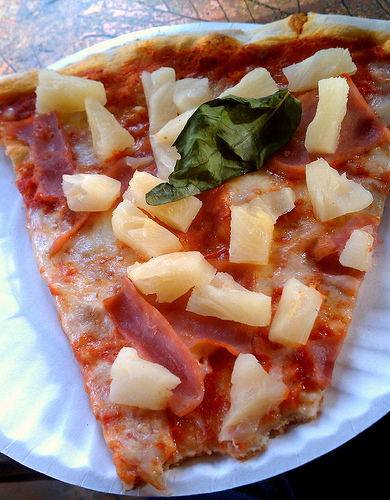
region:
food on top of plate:
[16, 9, 379, 499]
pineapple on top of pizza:
[95, 193, 317, 355]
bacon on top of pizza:
[74, 295, 199, 408]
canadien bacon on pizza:
[58, 275, 206, 403]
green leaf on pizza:
[122, 90, 308, 224]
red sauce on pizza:
[164, 387, 223, 434]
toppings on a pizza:
[59, 74, 282, 417]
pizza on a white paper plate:
[0, 25, 280, 446]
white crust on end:
[255, 10, 312, 46]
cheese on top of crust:
[290, 15, 301, 40]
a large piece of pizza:
[13, 39, 381, 483]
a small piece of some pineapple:
[96, 348, 168, 410]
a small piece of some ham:
[100, 276, 201, 401]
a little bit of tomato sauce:
[178, 416, 220, 463]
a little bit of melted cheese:
[100, 427, 167, 479]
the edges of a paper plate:
[8, 356, 70, 454]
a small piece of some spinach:
[135, 113, 274, 203]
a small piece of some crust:
[99, 40, 149, 85]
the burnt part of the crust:
[283, 16, 311, 43]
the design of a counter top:
[15, 15, 72, 59]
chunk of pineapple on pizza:
[284, 279, 297, 328]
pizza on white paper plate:
[347, 418, 369, 421]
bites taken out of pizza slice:
[137, 422, 334, 465]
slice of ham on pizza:
[135, 326, 172, 356]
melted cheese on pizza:
[82, 296, 94, 332]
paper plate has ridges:
[41, 413, 64, 439]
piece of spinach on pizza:
[213, 146, 235, 163]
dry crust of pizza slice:
[84, 40, 110, 55]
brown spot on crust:
[281, 9, 299, 25]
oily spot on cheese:
[132, 431, 147, 448]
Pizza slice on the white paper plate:
[1, 14, 380, 464]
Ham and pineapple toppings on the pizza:
[3, 32, 372, 467]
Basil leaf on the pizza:
[143, 85, 299, 202]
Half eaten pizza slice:
[0, 7, 379, 486]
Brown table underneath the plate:
[0, 21, 342, 494]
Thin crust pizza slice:
[3, 7, 382, 486]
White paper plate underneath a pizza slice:
[7, 8, 385, 486]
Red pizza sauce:
[1, 30, 177, 238]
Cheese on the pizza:
[27, 202, 130, 343]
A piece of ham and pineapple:
[105, 278, 201, 414]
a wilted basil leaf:
[141, 84, 305, 203]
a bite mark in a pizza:
[121, 440, 260, 484]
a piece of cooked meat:
[101, 276, 255, 419]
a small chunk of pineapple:
[271, 279, 326, 344]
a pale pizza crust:
[102, 10, 385, 67]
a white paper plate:
[1, 125, 379, 490]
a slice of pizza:
[12, 11, 379, 474]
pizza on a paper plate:
[14, 18, 385, 479]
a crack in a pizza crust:
[282, 6, 324, 34]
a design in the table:
[107, 1, 275, 29]